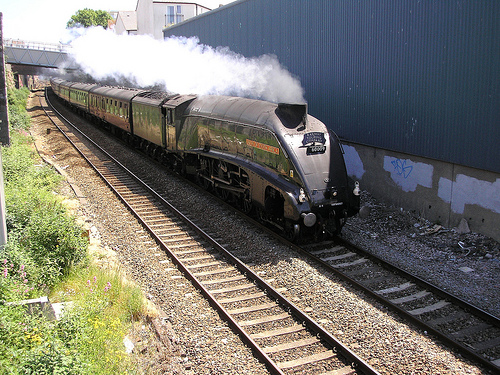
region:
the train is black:
[54, 45, 369, 278]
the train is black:
[168, 40, 425, 335]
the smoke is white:
[61, 15, 248, 109]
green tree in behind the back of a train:
[67, 4, 116, 31]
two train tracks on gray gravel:
[104, 247, 496, 372]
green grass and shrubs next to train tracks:
[0, 157, 155, 371]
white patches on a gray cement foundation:
[340, 144, 494, 229]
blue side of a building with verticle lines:
[195, 41, 492, 173]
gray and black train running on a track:
[46, 73, 366, 243]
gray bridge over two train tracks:
[2, 41, 82, 94]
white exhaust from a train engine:
[66, 27, 316, 105]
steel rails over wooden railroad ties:
[147, 229, 371, 363]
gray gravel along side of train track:
[26, 84, 250, 366]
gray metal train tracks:
[31, 91, 495, 373]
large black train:
[37, 72, 364, 232]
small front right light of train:
[296, 188, 311, 207]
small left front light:
[350, 180, 362, 196]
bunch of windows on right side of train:
[43, 82, 240, 152]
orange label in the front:
[245, 136, 280, 159]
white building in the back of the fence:
[99, 0, 205, 36]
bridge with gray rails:
[0, 38, 82, 69]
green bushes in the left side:
[4, 63, 134, 373]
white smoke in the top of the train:
[67, 23, 307, 103]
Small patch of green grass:
[65, 313, 102, 352]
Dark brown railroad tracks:
[50, 106, 236, 368]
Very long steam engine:
[36, 65, 363, 223]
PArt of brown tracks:
[332, 227, 498, 369]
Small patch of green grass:
[17, 212, 65, 260]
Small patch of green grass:
[9, 297, 58, 373]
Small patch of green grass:
[20, 260, 116, 330]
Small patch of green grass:
[70, 332, 112, 372]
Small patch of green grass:
[79, 270, 156, 333]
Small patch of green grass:
[19, 188, 74, 243]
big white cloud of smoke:
[64, 22, 299, 100]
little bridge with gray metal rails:
[2, 37, 104, 68]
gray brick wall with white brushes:
[342, 150, 499, 237]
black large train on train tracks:
[47, 73, 364, 231]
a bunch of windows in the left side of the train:
[47, 81, 176, 143]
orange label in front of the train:
[244, 138, 281, 158]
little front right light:
[297, 190, 305, 207]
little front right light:
[352, 186, 362, 199]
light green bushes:
[0, 69, 130, 371]